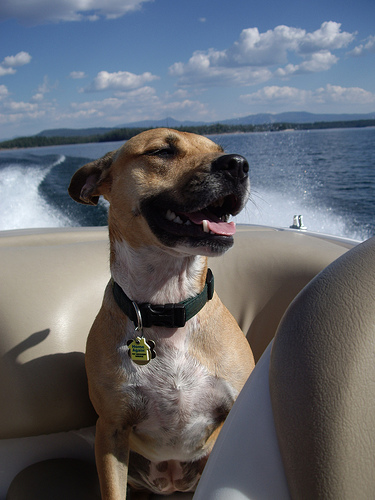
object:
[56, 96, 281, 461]
dog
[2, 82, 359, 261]
lake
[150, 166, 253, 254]
mouth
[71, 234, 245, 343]
collar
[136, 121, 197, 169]
eye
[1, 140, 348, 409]
boat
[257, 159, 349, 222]
splashing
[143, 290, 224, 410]
spot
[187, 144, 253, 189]
nose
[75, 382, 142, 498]
leg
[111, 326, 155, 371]
tag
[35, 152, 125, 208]
ear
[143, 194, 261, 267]
tongue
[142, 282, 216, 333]
clasp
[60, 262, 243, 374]
tags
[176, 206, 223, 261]
tooth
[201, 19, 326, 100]
cloud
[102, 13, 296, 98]
sky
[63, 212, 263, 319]
neck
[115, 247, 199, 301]
white part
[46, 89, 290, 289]
head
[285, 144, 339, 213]
water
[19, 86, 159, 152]
tree